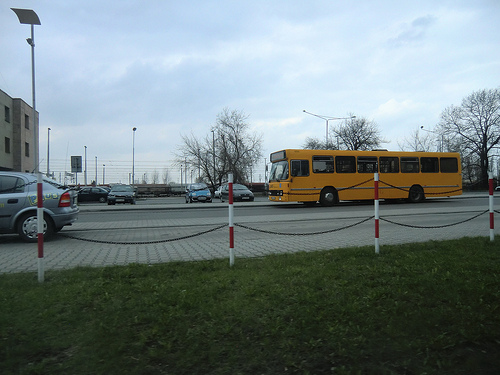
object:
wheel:
[405, 184, 424, 203]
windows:
[357, 156, 378, 173]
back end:
[27, 170, 80, 228]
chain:
[233, 214, 374, 240]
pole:
[373, 172, 380, 254]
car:
[185, 182, 213, 203]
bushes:
[395, 245, 498, 373]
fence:
[0, 172, 499, 283]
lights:
[128, 125, 139, 186]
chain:
[43, 179, 227, 199]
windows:
[312, 155, 334, 173]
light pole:
[83, 145, 88, 184]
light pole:
[43, 125, 51, 175]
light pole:
[304, 146, 358, 187]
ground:
[263, 207, 329, 219]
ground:
[412, 204, 442, 212]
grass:
[0, 236, 500, 375]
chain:
[377, 176, 488, 195]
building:
[0, 88, 39, 180]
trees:
[302, 112, 388, 150]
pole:
[33, 183, 45, 282]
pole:
[487, 172, 495, 241]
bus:
[268, 148, 464, 207]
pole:
[227, 173, 236, 267]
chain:
[43, 222, 228, 245]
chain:
[232, 214, 373, 235]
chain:
[379, 208, 489, 230]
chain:
[233, 177, 374, 195]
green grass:
[338, 286, 418, 336]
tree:
[171, 106, 263, 196]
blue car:
[185, 181, 213, 203]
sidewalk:
[166, 240, 222, 256]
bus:
[234, 217, 430, 275]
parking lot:
[78, 184, 139, 211]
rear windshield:
[43, 177, 71, 191]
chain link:
[231, 215, 373, 237]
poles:
[225, 173, 237, 268]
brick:
[175, 239, 224, 258]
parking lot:
[188, 191, 267, 205]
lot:
[1, 191, 35, 271]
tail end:
[48, 185, 77, 228]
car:
[0, 170, 80, 243]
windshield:
[270, 160, 289, 181]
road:
[83, 208, 186, 221]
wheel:
[319, 186, 338, 207]